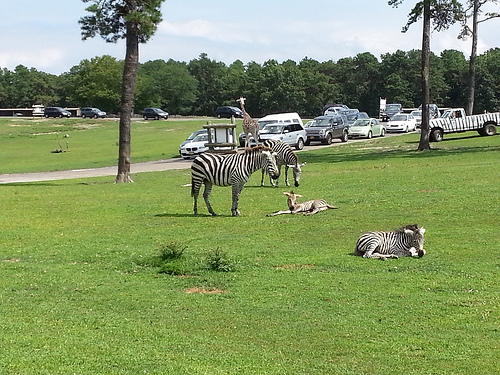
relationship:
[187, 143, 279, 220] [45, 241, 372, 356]
zebra in grass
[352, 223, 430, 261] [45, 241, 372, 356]
zebra in grass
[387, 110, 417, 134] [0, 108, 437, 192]
parked car on path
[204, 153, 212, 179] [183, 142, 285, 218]
stripe on zebra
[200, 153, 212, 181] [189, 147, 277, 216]
stripe on zebra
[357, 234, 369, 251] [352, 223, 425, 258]
stripe on zebra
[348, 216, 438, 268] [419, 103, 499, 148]
zebra on truck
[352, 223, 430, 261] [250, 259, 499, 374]
zebra in grass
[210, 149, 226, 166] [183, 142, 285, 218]
stripe on zebra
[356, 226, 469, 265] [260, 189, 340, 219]
adult zebras behind zebra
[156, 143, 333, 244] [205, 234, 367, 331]
zebra in grass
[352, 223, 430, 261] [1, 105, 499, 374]
zebra on ground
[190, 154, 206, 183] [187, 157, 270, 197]
stripe on zebra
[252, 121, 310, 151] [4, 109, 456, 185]
car at street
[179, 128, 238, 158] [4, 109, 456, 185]
car at street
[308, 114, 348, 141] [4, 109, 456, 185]
car at street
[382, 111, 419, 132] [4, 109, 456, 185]
car at street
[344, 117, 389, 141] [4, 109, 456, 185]
car at street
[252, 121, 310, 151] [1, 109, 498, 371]
car driving through zoo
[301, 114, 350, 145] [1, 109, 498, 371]
car driving through zoo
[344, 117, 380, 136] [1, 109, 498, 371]
car driving through zoo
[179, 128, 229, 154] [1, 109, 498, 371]
car driving through zoo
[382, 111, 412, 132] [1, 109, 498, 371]
car driving through zoo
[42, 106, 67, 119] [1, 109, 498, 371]
car driving through zoo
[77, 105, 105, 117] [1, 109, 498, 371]
car driving through zoo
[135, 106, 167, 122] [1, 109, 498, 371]
car driving through zoo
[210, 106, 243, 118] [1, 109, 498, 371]
car driving through zoo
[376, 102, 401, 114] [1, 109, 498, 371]
car driving through zoo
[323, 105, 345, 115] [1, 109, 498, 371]
car driving through zoo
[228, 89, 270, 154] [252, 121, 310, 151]
giraffe crossing in front of car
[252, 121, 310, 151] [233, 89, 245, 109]
car with head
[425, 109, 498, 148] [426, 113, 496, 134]
truck painted in stripes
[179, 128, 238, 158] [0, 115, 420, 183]
car on a path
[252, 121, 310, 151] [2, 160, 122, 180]
car on a path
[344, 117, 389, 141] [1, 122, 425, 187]
car on a path